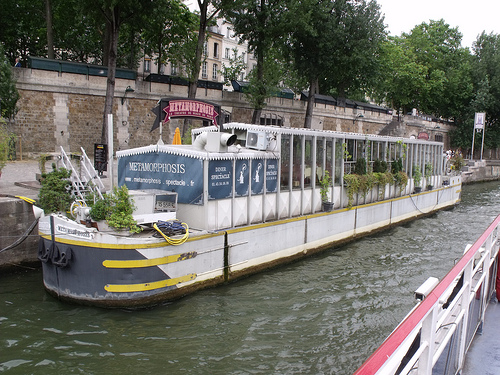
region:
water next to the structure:
[277, 276, 339, 331]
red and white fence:
[390, 266, 456, 343]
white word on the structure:
[120, 155, 190, 180]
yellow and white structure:
[170, 237, 205, 283]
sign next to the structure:
[158, 93, 228, 135]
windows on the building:
[199, 55, 224, 84]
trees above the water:
[274, 18, 466, 100]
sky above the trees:
[395, 14, 415, 32]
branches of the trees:
[19, 25, 262, 104]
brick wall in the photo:
[23, 105, 50, 136]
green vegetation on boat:
[28, 163, 148, 230]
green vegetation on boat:
[346, 170, 413, 195]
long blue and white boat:
[31, 118, 463, 310]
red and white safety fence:
[367, 210, 489, 374]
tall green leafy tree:
[237, 4, 294, 117]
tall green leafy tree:
[303, 2, 387, 115]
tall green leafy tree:
[375, 22, 485, 140]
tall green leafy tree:
[462, 35, 499, 151]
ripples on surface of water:
[202, 310, 307, 370]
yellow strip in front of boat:
[96, 248, 198, 288]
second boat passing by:
[353, 212, 497, 372]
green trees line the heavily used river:
[0, 1, 498, 158]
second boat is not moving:
[33, 120, 463, 305]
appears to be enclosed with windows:
[191, 120, 443, 192]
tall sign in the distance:
[470, 110, 486, 164]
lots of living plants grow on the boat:
[39, 138, 451, 230]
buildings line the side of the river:
[137, 6, 265, 82]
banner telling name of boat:
[147, 95, 224, 129]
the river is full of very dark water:
[1, 175, 498, 371]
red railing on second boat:
[354, 213, 497, 373]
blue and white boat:
[37, 124, 466, 305]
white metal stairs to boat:
[57, 145, 109, 214]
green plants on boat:
[36, 161, 132, 238]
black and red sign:
[149, 96, 233, 128]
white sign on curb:
[474, 110, 486, 131]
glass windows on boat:
[281, 133, 444, 190]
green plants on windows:
[316, 159, 410, 199]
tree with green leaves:
[286, 2, 388, 130]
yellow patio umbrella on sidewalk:
[171, 126, 181, 146]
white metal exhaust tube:
[193, 130, 234, 149]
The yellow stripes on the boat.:
[105, 251, 207, 300]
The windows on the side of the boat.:
[275, 133, 446, 188]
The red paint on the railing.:
[351, 224, 497, 374]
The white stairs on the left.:
[55, 147, 106, 204]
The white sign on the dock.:
[472, 108, 489, 160]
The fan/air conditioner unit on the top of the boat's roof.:
[240, 122, 272, 150]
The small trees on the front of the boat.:
[42, 166, 142, 226]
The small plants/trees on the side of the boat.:
[313, 140, 465, 195]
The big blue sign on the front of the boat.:
[131, 154, 201, 201]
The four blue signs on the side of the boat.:
[207, 157, 278, 200]